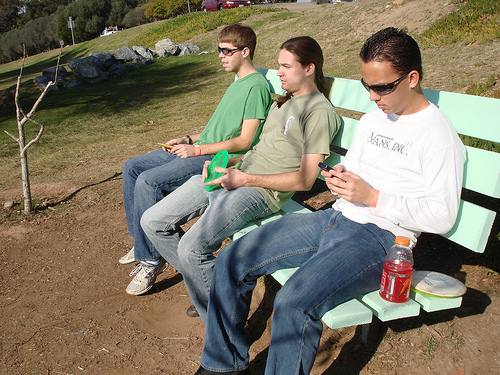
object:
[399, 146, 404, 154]
letter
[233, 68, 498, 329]
bench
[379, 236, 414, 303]
bottle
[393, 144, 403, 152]
black letter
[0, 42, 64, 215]
tree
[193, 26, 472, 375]
man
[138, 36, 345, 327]
man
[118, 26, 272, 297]
man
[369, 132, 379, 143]
letter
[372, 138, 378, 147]
letter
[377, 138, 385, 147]
letter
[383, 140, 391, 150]
letter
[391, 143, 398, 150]
letter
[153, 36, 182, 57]
rocks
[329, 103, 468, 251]
shirt